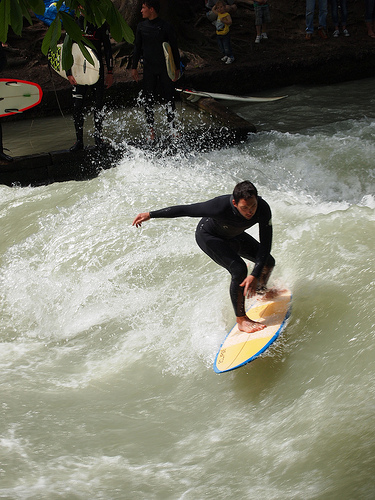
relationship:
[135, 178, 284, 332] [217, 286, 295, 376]
man on board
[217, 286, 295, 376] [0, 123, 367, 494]
board above water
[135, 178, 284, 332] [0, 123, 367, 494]
man on water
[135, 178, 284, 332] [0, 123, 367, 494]
man above water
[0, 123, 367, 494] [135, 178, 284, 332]
water below man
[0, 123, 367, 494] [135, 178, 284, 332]
water under man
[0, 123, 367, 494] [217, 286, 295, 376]
water under board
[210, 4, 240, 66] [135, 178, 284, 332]
kid behind man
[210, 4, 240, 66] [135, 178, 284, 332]
kid watching man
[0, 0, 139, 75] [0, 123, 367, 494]
tree above water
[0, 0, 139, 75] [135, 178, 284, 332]
tree above man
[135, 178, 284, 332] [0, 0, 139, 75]
man under tree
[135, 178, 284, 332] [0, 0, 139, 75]
man below tree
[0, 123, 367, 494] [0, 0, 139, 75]
water below tree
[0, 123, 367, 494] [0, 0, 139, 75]
water under tree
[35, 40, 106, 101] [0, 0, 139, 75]
surfboard under tree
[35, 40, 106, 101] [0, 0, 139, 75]
surfboard below tree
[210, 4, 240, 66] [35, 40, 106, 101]
kid behind surfboard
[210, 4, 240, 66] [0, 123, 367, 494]
kid close to water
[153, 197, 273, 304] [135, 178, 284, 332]
wet suit on man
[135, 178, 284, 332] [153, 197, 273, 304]
man wearing wet suit